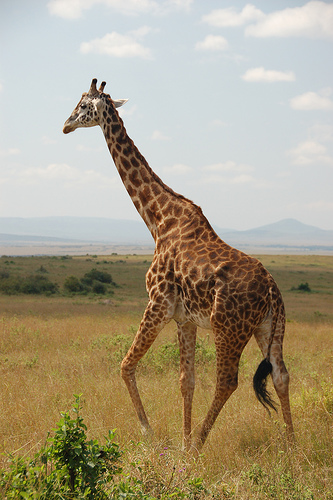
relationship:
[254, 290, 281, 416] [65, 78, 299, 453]
tail attached to giraffe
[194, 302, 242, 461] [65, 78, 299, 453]
leg belongs to giraffe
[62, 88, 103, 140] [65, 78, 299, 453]
face belongs to giraffe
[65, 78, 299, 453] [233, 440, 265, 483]
giraffe on top of grass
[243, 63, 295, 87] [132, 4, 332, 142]
cloud flying within sky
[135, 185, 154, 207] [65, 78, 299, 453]
spot colored on giraffe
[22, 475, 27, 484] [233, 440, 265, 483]
flower near grass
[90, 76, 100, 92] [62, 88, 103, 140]
horn on top of face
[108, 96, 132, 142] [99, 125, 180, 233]
hair along neck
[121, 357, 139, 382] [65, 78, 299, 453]
knee belongs to giraffe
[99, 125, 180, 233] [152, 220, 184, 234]
neck contains wrinkles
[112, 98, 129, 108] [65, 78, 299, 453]
ear belongs to giraffe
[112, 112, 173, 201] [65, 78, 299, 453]
mane belongs to giraffe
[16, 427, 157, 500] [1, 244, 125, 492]
wildflowers on top of field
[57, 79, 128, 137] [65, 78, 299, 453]
head belongs to giraffe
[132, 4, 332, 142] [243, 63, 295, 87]
sky contains a cloud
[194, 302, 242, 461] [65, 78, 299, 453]
leg belongs to a giraffe